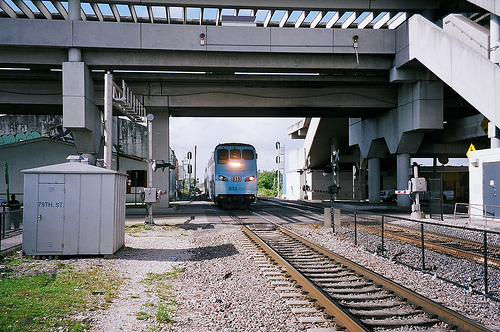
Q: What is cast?
A: Shadow.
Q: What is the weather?
A: Sunny.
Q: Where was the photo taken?
A: Railway.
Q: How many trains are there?
A: One.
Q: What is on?
A: Headlights.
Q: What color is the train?
A: Blue.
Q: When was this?
A: Daytime.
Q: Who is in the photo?
A: No one.